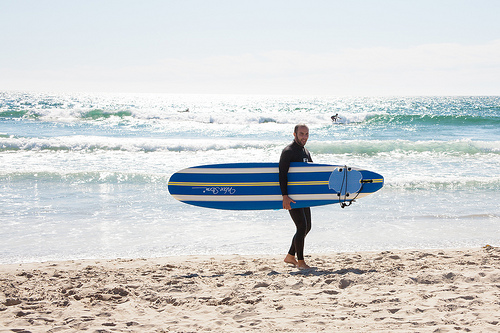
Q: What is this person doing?
A: Surfing.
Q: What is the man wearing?
A: A wetsuit.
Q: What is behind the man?
A: Water.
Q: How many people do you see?
A: 2.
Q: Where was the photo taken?
A: At the beach.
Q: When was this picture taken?
A: During daylight.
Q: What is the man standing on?
A: Sand.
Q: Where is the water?
A: Behind the man with a surfboard.